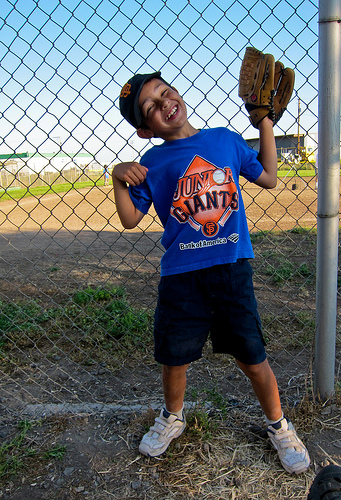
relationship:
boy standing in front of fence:
[111, 47, 311, 473] [0, 0, 340, 415]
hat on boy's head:
[219, 34, 271, 107] [118, 71, 185, 139]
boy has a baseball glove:
[111, 47, 311, 477] [241, 46, 297, 131]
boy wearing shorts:
[111, 47, 311, 473] [153, 257, 266, 365]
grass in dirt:
[5, 415, 83, 494] [13, 414, 137, 486]